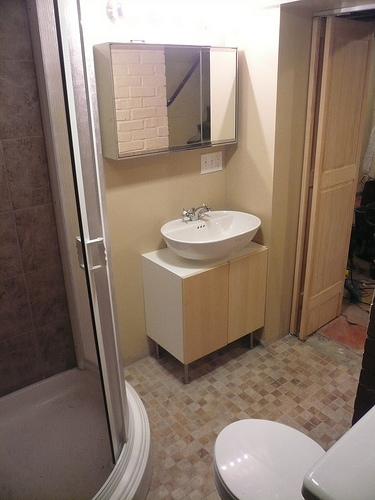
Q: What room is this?
A: It is a bathroom.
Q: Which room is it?
A: It is a bathroom.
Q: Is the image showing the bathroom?
A: Yes, it is showing the bathroom.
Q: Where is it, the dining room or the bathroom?
A: It is the bathroom.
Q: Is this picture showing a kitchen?
A: No, the picture is showing a bathroom.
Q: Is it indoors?
A: Yes, it is indoors.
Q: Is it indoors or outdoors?
A: It is indoors.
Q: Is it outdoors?
A: No, it is indoors.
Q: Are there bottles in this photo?
A: No, there are no bottles.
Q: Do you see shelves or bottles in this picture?
A: No, there are no bottles or shelves.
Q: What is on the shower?
A: The tiles are on the shower.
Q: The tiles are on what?
A: The tiles are on the shower.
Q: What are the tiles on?
A: The tiles are on the shower.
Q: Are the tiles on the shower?
A: Yes, the tiles are on the shower.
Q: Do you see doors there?
A: Yes, there is a door.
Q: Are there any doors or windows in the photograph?
A: Yes, there is a door.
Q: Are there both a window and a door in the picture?
A: No, there is a door but no windows.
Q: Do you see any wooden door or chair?
A: Yes, there is a wood door.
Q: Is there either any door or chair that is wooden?
A: Yes, the door is wooden.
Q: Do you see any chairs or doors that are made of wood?
A: Yes, the door is made of wood.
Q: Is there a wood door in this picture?
A: Yes, there is a wood door.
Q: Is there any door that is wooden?
A: Yes, there is a door that is wooden.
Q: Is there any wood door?
A: Yes, there is a door that is made of wood.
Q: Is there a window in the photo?
A: No, there are no windows.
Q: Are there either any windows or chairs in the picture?
A: No, there are no windows or chairs.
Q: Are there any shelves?
A: No, there are no shelves.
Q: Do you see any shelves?
A: No, there are no shelves.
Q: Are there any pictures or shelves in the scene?
A: No, there are no shelves or pictures.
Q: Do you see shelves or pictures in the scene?
A: No, there are no shelves or pictures.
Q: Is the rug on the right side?
A: Yes, the rug is on the right of the image.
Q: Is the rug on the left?
A: No, the rug is on the right of the image.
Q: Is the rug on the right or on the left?
A: The rug is on the right of the image.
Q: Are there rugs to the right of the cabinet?
A: Yes, there is a rug to the right of the cabinet.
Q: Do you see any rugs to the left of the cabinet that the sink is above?
A: No, the rug is to the right of the cabinet.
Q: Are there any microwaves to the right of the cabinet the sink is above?
A: No, there is a rug to the right of the cabinet.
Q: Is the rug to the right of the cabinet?
A: Yes, the rug is to the right of the cabinet.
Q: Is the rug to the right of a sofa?
A: No, the rug is to the right of the cabinet.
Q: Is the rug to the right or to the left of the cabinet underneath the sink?
A: The rug is to the right of the cabinet.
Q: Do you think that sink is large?
A: Yes, the sink is large.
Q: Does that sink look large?
A: Yes, the sink is large.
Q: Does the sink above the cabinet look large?
A: Yes, the sink is large.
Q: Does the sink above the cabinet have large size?
A: Yes, the sink is large.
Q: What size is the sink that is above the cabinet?
A: The sink is large.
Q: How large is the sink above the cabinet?
A: The sink is large.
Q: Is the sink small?
A: No, the sink is large.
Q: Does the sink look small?
A: No, the sink is large.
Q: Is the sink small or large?
A: The sink is large.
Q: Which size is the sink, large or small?
A: The sink is large.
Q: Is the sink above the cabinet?
A: Yes, the sink is above the cabinet.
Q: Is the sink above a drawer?
A: No, the sink is above the cabinet.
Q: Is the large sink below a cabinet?
A: No, the sink is above a cabinet.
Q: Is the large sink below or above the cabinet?
A: The sink is above the cabinet.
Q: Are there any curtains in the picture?
A: No, there are no curtains.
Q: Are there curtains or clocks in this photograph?
A: No, there are no curtains or clocks.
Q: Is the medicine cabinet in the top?
A: Yes, the medicine cabinet is in the top of the image.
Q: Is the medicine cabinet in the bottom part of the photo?
A: No, the medicine cabinet is in the top of the image.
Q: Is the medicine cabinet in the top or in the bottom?
A: The medicine cabinet is in the top of the image.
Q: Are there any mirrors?
A: Yes, there is a mirror.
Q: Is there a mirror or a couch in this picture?
A: Yes, there is a mirror.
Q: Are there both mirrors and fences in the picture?
A: No, there is a mirror but no fences.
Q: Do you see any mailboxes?
A: No, there are no mailboxes.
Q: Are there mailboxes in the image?
A: No, there are no mailboxes.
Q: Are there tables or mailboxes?
A: No, there are no mailboxes or tables.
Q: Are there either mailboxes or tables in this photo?
A: No, there are no mailboxes or tables.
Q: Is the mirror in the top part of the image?
A: Yes, the mirror is in the top of the image.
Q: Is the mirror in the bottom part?
A: No, the mirror is in the top of the image.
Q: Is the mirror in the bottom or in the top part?
A: The mirror is in the top of the image.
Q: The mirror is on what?
A: The mirror is on the wall.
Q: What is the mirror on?
A: The mirror is on the wall.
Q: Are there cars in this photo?
A: No, there are no cars.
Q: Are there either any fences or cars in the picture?
A: No, there are no cars or fences.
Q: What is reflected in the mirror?
A: The staircase is reflected in the mirror.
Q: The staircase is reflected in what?
A: The staircase is reflected in the mirror.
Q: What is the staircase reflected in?
A: The staircase is reflected in the mirror.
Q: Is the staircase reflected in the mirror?
A: Yes, the staircase is reflected in the mirror.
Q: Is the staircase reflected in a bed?
A: No, the staircase is reflected in the mirror.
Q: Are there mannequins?
A: No, there are no mannequins.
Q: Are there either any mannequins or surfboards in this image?
A: No, there are no mannequins or surfboards.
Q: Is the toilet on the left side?
A: No, the toilet is on the right of the image.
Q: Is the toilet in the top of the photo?
A: No, the toilet is in the bottom of the image.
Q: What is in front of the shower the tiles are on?
A: The toilet is in front of the shower.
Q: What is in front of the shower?
A: The toilet is in front of the shower.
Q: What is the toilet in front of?
A: The toilet is in front of the shower.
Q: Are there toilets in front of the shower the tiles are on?
A: Yes, there is a toilet in front of the shower.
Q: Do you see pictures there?
A: No, there are no pictures.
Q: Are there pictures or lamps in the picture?
A: No, there are no pictures or lamps.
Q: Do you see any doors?
A: Yes, there is a door.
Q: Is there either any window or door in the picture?
A: Yes, there is a door.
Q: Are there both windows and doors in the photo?
A: No, there is a door but no windows.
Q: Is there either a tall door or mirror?
A: Yes, there is a tall door.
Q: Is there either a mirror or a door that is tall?
A: Yes, the door is tall.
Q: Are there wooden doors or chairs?
A: Yes, there is a wood door.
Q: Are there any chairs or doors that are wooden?
A: Yes, the door is wooden.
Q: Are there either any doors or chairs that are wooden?
A: Yes, the door is wooden.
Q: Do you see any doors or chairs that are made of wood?
A: Yes, the door is made of wood.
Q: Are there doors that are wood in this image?
A: Yes, there is a wood door.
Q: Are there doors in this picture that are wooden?
A: Yes, there is a door that is wooden.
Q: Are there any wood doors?
A: Yes, there is a door that is made of wood.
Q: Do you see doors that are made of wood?
A: Yes, there is a door that is made of wood.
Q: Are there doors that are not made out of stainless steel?
A: Yes, there is a door that is made of wood.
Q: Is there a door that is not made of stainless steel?
A: Yes, there is a door that is made of wood.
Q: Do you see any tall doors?
A: Yes, there is a tall door.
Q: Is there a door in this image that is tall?
A: Yes, there is a door that is tall.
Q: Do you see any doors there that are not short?
A: Yes, there is a tall door.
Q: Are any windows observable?
A: No, there are no windows.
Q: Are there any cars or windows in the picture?
A: No, there are no windows or cars.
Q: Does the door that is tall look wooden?
A: Yes, the door is wooden.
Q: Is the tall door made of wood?
A: Yes, the door is made of wood.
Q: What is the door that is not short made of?
A: The door is made of wood.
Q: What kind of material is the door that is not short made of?
A: The door is made of wood.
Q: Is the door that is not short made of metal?
A: No, the door is made of wood.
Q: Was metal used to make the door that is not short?
A: No, the door is made of wood.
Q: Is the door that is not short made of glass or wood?
A: The door is made of wood.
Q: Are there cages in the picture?
A: No, there are no cages.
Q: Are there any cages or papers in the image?
A: No, there are no cages or papers.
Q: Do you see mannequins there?
A: No, there are no mannequins.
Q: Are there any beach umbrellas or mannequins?
A: No, there are no mannequins or beach umbrellas.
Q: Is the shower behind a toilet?
A: Yes, the shower is behind a toilet.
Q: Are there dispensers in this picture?
A: No, there are no dispensers.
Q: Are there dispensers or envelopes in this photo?
A: No, there are no dispensers or envelopes.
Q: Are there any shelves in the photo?
A: No, there are no shelves.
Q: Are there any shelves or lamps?
A: No, there are no shelves or lamps.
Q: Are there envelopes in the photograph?
A: No, there are no envelopes.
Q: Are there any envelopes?
A: No, there are no envelopes.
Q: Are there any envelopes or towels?
A: No, there are no envelopes or towels.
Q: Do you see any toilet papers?
A: No, there are no toilet papers.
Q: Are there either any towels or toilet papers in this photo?
A: No, there are no toilet papers or towels.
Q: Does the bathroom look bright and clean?
A: Yes, the bathroom is bright and clean.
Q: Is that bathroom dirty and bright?
A: No, the bathroom is bright but clean.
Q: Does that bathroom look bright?
A: Yes, the bathroom is bright.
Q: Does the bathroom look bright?
A: Yes, the bathroom is bright.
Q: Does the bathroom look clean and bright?
A: Yes, the bathroom is clean and bright.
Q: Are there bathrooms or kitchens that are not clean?
A: No, there is a bathroom but it is clean.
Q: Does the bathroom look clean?
A: Yes, the bathroom is clean.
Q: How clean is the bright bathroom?
A: The bathroom is clean.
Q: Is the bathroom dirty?
A: No, the bathroom is clean.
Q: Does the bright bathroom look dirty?
A: No, the bathroom is clean.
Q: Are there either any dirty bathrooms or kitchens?
A: No, there is a bathroom but it is clean.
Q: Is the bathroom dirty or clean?
A: The bathroom is clean.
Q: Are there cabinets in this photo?
A: Yes, there is a cabinet.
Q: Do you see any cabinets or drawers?
A: Yes, there is a cabinet.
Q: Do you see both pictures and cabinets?
A: No, there is a cabinet but no pictures.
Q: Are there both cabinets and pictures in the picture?
A: No, there is a cabinet but no pictures.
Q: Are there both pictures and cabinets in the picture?
A: No, there is a cabinet but no pictures.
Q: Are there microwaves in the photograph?
A: No, there are no microwaves.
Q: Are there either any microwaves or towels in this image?
A: No, there are no microwaves or towels.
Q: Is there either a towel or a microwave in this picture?
A: No, there are no microwaves or towels.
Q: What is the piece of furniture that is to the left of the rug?
A: The piece of furniture is a cabinet.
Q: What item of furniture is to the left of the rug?
A: The piece of furniture is a cabinet.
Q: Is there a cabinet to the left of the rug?
A: Yes, there is a cabinet to the left of the rug.